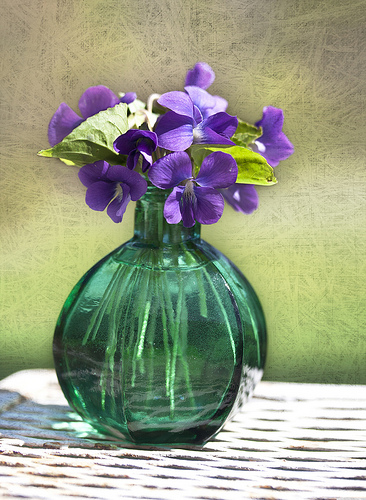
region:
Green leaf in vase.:
[221, 118, 259, 189]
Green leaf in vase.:
[70, 109, 112, 154]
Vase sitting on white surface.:
[58, 386, 242, 466]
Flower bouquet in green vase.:
[62, 153, 269, 227]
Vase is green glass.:
[67, 355, 250, 418]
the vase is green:
[51, 177, 304, 465]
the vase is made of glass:
[23, 229, 282, 431]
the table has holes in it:
[2, 368, 321, 498]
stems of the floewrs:
[63, 247, 234, 379]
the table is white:
[2, 384, 300, 482]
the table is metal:
[0, 417, 289, 498]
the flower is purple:
[142, 145, 252, 231]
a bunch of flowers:
[36, 77, 284, 244]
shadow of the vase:
[5, 376, 81, 454]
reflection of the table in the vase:
[213, 340, 284, 438]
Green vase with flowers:
[46, 69, 287, 449]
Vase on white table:
[20, 367, 353, 489]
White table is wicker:
[3, 436, 354, 494]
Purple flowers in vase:
[52, 69, 288, 235]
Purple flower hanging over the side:
[144, 147, 237, 229]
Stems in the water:
[77, 242, 244, 423]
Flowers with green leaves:
[30, 96, 285, 189]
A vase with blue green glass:
[48, 210, 270, 455]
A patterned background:
[8, 5, 360, 85]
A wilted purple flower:
[107, 121, 162, 177]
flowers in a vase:
[37, 66, 306, 468]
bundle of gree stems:
[87, 252, 227, 409]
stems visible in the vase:
[55, 245, 263, 443]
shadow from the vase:
[1, 380, 95, 452]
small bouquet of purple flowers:
[38, 62, 294, 226]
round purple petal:
[194, 150, 238, 190]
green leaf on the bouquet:
[28, 104, 161, 172]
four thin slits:
[204, 456, 321, 483]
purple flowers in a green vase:
[41, 49, 297, 456]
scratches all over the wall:
[2, 0, 364, 384]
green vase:
[44, 185, 282, 451]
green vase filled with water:
[48, 236, 266, 448]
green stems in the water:
[79, 248, 245, 445]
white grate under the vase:
[1, 351, 364, 499]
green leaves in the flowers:
[33, 88, 278, 195]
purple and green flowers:
[41, 61, 293, 230]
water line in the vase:
[107, 243, 228, 274]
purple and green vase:
[19, 61, 302, 444]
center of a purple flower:
[180, 169, 206, 203]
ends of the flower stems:
[86, 387, 228, 428]